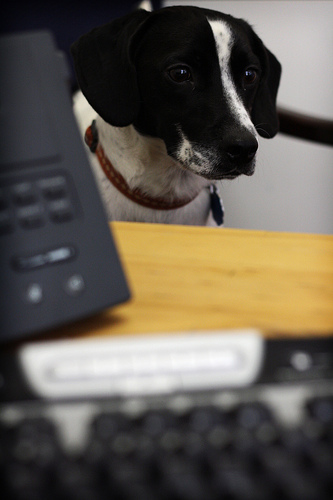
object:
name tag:
[208, 182, 226, 226]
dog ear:
[68, 7, 151, 132]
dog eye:
[165, 63, 197, 85]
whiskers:
[177, 151, 200, 177]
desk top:
[38, 220, 333, 343]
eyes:
[240, 62, 258, 86]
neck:
[88, 112, 210, 212]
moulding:
[272, 100, 333, 148]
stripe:
[208, 17, 258, 141]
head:
[71, 6, 284, 182]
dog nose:
[225, 118, 260, 163]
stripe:
[205, 15, 260, 148]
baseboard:
[272, 102, 333, 149]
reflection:
[178, 67, 183, 73]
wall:
[160, 1, 333, 234]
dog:
[69, 0, 283, 225]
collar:
[83, 118, 206, 212]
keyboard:
[0, 330, 333, 500]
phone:
[0, 26, 132, 347]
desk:
[0, 221, 333, 362]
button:
[48, 200, 70, 222]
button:
[12, 174, 35, 206]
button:
[16, 200, 48, 231]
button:
[13, 249, 47, 275]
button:
[65, 272, 83, 297]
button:
[25, 279, 45, 306]